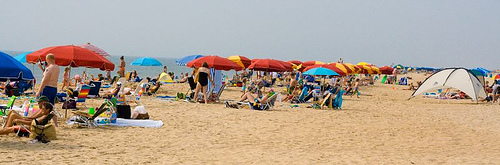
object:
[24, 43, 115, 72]
umbrella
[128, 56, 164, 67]
umbrella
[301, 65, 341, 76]
umbrella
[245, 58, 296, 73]
umbrella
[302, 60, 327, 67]
umbrella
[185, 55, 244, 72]
umbrella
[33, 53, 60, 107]
person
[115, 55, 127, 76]
person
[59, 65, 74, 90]
person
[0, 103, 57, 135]
person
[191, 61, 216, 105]
person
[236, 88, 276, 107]
person